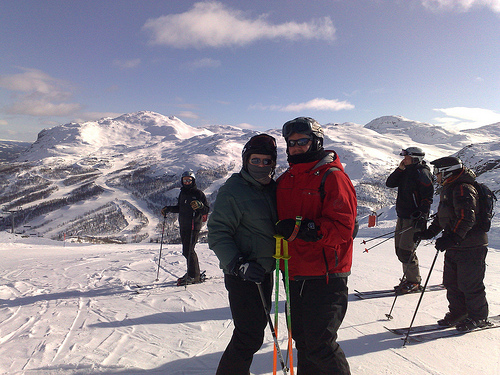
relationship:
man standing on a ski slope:
[275, 116, 357, 375] [4, 235, 499, 375]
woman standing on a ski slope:
[207, 132, 278, 374] [4, 235, 499, 375]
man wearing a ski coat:
[275, 116, 357, 375] [275, 150, 358, 281]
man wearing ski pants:
[275, 116, 357, 375] [283, 277, 351, 375]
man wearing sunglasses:
[275, 116, 357, 375] [287, 137, 311, 147]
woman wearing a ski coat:
[207, 132, 278, 374] [207, 170, 277, 272]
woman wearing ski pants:
[207, 132, 278, 374] [216, 274, 273, 374]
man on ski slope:
[413, 156, 489, 331] [4, 235, 499, 375]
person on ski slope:
[385, 147, 436, 293] [4, 235, 499, 375]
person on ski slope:
[161, 171, 209, 285] [4, 235, 499, 375]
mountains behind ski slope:
[1, 109, 500, 241] [4, 235, 499, 375]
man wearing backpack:
[413, 156, 489, 331] [460, 179, 498, 233]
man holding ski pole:
[413, 156, 489, 331] [402, 249, 440, 347]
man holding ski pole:
[413, 156, 489, 331] [384, 237, 422, 320]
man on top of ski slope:
[275, 116, 357, 375] [4, 235, 499, 375]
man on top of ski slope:
[413, 156, 489, 331] [4, 235, 499, 375]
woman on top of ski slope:
[207, 132, 278, 374] [4, 235, 499, 375]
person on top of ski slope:
[385, 147, 436, 293] [4, 235, 499, 375]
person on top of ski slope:
[161, 171, 209, 285] [4, 235, 499, 375]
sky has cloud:
[0, 1, 499, 144] [139, 1, 339, 53]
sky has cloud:
[0, 1, 499, 144] [249, 96, 356, 111]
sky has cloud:
[0, 1, 499, 144] [4, 64, 81, 118]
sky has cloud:
[0, 1, 499, 144] [420, 0, 499, 16]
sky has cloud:
[0, 1, 499, 144] [112, 56, 143, 70]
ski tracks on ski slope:
[2, 247, 230, 372] [4, 235, 499, 375]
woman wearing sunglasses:
[207, 132, 278, 374] [248, 157, 273, 165]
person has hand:
[385, 147, 436, 293] [400, 159, 406, 170]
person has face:
[385, 147, 436, 293] [403, 154, 411, 166]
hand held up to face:
[400, 159, 406, 170] [403, 154, 411, 166]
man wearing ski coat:
[275, 116, 357, 375] [275, 150, 358, 281]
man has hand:
[275, 116, 357, 375] [275, 220, 302, 240]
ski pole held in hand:
[283, 238, 295, 374] [275, 220, 302, 240]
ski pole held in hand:
[271, 233, 286, 374] [275, 220, 302, 240]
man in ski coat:
[275, 116, 357, 375] [275, 150, 358, 281]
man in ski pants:
[275, 116, 357, 375] [283, 277, 351, 375]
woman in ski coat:
[207, 132, 278, 374] [207, 170, 277, 272]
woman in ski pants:
[207, 132, 278, 374] [216, 274, 273, 374]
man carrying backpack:
[413, 156, 489, 331] [460, 179, 498, 233]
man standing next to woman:
[275, 116, 357, 375] [207, 132, 278, 374]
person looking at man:
[161, 171, 209, 285] [275, 116, 357, 375]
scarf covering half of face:
[248, 162, 272, 183] [249, 149, 272, 179]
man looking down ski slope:
[413, 156, 489, 331] [4, 235, 499, 375]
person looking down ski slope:
[385, 147, 436, 293] [4, 235, 499, 375]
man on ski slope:
[275, 116, 357, 375] [4, 235, 499, 375]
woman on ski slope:
[207, 132, 278, 374] [4, 235, 499, 375]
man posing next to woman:
[275, 116, 357, 375] [207, 132, 278, 374]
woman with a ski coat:
[207, 132, 278, 374] [207, 170, 277, 272]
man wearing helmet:
[275, 116, 357, 375] [287, 115, 325, 151]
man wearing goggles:
[275, 116, 357, 375] [281, 120, 324, 135]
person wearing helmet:
[385, 147, 436, 293] [403, 147, 426, 162]